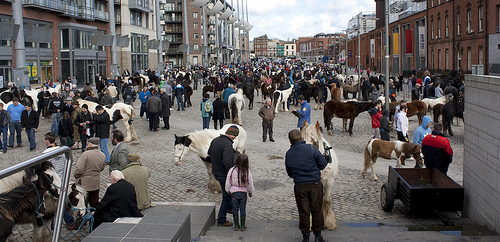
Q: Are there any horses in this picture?
A: Yes, there is a horse.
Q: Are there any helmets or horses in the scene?
A: Yes, there is a horse.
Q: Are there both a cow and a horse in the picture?
A: No, there is a horse but no cows.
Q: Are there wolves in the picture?
A: No, there are no wolves.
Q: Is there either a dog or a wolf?
A: No, there are no wolves or dogs.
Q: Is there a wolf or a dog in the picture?
A: No, there are no wolves or dogs.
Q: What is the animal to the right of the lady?
A: The animal is a horse.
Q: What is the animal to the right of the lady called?
A: The animal is a horse.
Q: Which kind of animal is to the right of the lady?
A: The animal is a horse.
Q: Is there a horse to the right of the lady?
A: Yes, there is a horse to the right of the lady.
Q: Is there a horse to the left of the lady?
A: No, the horse is to the right of the lady.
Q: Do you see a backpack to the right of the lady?
A: No, there is a horse to the right of the lady.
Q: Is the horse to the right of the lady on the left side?
A: Yes, the horse is to the right of the lady.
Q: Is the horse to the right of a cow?
A: No, the horse is to the right of the lady.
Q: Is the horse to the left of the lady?
A: No, the horse is to the right of the lady.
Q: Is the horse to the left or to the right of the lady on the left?
A: The horse is to the right of the lady.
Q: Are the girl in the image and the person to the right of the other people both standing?
A: Yes, both the girl and the person are standing.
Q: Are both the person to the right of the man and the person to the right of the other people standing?
A: Yes, both the girl and the person are standing.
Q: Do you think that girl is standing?
A: Yes, the girl is standing.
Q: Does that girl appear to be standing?
A: Yes, the girl is standing.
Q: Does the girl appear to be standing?
A: Yes, the girl is standing.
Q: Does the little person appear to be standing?
A: Yes, the girl is standing.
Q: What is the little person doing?
A: The girl is standing.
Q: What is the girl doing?
A: The girl is standing.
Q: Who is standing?
A: The girl is standing.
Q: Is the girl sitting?
A: No, the girl is standing.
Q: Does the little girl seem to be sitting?
A: No, the girl is standing.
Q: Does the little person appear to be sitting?
A: No, the girl is standing.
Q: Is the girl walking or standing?
A: The girl is standing.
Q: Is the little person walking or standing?
A: The girl is standing.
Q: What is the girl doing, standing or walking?
A: The girl is standing.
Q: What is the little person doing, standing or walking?
A: The girl is standing.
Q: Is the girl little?
A: Yes, the girl is little.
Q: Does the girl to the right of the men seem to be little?
A: Yes, the girl is little.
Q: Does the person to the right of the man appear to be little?
A: Yes, the girl is little.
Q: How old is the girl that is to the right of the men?
A: The girl is little.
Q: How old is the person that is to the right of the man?
A: The girl is little.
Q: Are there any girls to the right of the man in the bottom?
A: Yes, there is a girl to the right of the man.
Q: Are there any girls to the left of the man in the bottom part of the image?
A: No, the girl is to the right of the man.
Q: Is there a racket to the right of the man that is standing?
A: No, there is a girl to the right of the man.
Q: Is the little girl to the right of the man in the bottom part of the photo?
A: Yes, the girl is to the right of the man.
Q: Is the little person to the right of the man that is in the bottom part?
A: Yes, the girl is to the right of the man.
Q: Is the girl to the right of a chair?
A: No, the girl is to the right of the man.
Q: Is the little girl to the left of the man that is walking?
A: No, the girl is to the right of the man.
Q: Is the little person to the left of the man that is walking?
A: No, the girl is to the right of the man.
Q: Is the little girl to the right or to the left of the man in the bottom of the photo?
A: The girl is to the right of the man.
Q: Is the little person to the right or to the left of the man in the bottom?
A: The girl is to the right of the man.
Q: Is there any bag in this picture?
A: No, there are no bags.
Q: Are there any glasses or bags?
A: No, there are no bags or glasses.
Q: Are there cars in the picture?
A: No, there are no cars.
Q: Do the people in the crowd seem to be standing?
A: Yes, the people are standing.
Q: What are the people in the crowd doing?
A: The people are standing.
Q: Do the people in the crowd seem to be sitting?
A: No, the people are standing.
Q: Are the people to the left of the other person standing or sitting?
A: The people are standing.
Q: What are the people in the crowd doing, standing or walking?
A: The people are standing.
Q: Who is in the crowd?
A: The people are in the crowd.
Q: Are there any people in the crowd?
A: Yes, there are people in the crowd.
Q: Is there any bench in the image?
A: No, there are no benches.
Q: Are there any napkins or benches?
A: No, there are no benches or napkins.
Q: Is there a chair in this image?
A: No, there are no chairs.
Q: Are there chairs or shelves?
A: No, there are no chairs or shelves.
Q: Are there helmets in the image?
A: No, there are no helmets.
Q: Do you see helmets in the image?
A: No, there are no helmets.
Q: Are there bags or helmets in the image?
A: No, there are no helmets or bags.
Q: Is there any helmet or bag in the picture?
A: No, there are no helmets or bags.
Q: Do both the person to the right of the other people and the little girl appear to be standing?
A: Yes, both the person and the girl are standing.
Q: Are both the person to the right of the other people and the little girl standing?
A: Yes, both the person and the girl are standing.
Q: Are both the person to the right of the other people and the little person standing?
A: Yes, both the person and the girl are standing.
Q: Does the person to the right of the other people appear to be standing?
A: Yes, the person is standing.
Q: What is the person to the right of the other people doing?
A: The person is standing.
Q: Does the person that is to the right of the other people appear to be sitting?
A: No, the person is standing.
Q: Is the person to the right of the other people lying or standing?
A: The person is standing.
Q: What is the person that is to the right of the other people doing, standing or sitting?
A: The person is standing.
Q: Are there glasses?
A: No, there are no glasses.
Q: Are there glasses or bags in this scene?
A: No, there are no glasses or bags.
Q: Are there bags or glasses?
A: No, there are no glasses or bags.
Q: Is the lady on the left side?
A: Yes, the lady is on the left of the image.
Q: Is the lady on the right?
A: No, the lady is on the left of the image.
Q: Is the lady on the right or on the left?
A: The lady is on the left of the image.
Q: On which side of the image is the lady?
A: The lady is on the left of the image.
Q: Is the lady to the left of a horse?
A: Yes, the lady is to the left of a horse.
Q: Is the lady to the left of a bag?
A: No, the lady is to the left of a horse.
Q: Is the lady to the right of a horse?
A: No, the lady is to the left of a horse.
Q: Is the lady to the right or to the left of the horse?
A: The lady is to the left of the horse.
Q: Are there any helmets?
A: No, there are no helmets.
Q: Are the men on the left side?
A: Yes, the men are on the left of the image.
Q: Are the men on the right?
A: No, the men are on the left of the image.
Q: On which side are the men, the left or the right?
A: The men are on the left of the image.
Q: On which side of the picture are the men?
A: The men are on the left of the image.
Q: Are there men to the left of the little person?
A: Yes, there are men to the left of the girl.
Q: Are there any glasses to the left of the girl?
A: No, there are men to the left of the girl.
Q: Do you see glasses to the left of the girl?
A: No, there are men to the left of the girl.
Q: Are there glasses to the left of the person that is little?
A: No, there are men to the left of the girl.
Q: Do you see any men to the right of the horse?
A: No, the men are to the left of the horse.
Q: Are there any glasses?
A: No, there are no glasses.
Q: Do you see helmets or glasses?
A: No, there are no glasses or helmets.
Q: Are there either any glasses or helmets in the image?
A: No, there are no glasses or helmets.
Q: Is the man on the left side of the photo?
A: Yes, the man is on the left of the image.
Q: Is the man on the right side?
A: No, the man is on the left of the image.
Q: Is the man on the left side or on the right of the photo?
A: The man is on the left of the image.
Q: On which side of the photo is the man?
A: The man is on the left of the image.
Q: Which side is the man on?
A: The man is on the left of the image.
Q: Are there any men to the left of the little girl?
A: Yes, there is a man to the left of the girl.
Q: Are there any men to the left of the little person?
A: Yes, there is a man to the left of the girl.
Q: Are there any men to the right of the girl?
A: No, the man is to the left of the girl.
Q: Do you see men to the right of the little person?
A: No, the man is to the left of the girl.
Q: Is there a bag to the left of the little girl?
A: No, there is a man to the left of the girl.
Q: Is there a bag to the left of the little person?
A: No, there is a man to the left of the girl.